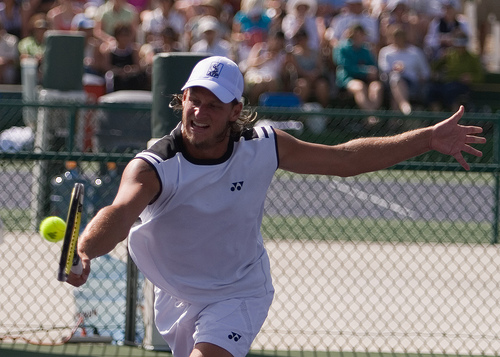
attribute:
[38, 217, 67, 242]
ball — yellow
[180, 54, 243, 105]
cap — white, baseball ,  block the sun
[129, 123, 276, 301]
shirt — black, white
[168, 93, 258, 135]
hair — long, shoulder length, blond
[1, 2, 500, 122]
audience — large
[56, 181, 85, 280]
racket — yellow, black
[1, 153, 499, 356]
fence — metal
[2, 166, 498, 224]
court — paved